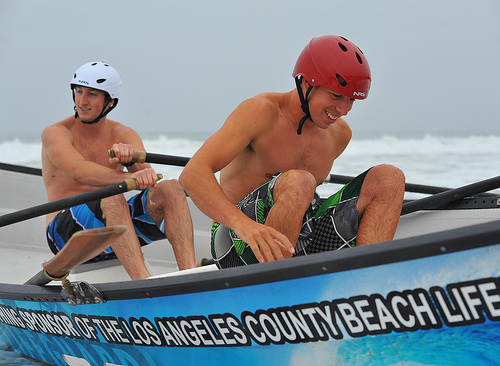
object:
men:
[176, 30, 409, 272]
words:
[68, 309, 103, 343]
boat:
[1, 158, 499, 365]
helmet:
[287, 30, 377, 102]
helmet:
[74, 62, 128, 102]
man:
[38, 60, 198, 287]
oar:
[105, 148, 500, 197]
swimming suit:
[42, 183, 171, 265]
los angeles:
[117, 311, 254, 348]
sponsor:
[11, 305, 80, 339]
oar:
[400, 172, 499, 216]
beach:
[329, 284, 446, 336]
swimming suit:
[207, 165, 379, 276]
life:
[426, 273, 500, 329]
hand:
[235, 218, 300, 265]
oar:
[0, 172, 167, 228]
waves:
[321, 127, 498, 193]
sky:
[1, 0, 499, 131]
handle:
[124, 169, 165, 193]